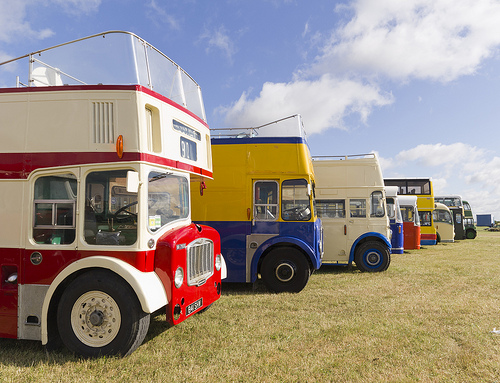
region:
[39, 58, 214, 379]
truck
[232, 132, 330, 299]
blue and yellow truck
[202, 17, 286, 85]
white clouds in blue sky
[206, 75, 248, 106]
white clouds in blue sky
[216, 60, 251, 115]
white clouds in blue sky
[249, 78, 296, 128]
white clouds in blue sky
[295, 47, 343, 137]
white clouds in blue sky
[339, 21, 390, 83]
white clouds in blue sky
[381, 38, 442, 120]
white clouds in blue sky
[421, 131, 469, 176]
white clouds in blue sky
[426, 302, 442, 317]
part of a field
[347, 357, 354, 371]
part of a lawn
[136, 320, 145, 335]
part of a wheel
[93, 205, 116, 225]
part of a window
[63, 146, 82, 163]
side of a bus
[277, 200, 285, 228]
edge of a bus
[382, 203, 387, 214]
edge of a bus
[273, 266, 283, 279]
part of a wheel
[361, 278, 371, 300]
part of a lawn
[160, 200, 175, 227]
part of a window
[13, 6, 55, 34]
white clouds in blue sky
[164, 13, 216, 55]
white clouds in blue sky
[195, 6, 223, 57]
white clouds in blue sky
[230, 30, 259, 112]
white clouds in blue sky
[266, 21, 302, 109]
white clouds in blue sky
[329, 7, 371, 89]
white clouds in blue sky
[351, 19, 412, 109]
white clouds in blue sky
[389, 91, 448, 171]
white clouds in blue sky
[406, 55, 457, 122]
white clouds in blue sky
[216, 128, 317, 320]
the RV is yellow and blue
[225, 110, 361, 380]
the RV is yellow and blue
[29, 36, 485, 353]
the buses are parked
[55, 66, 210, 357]
red and white truck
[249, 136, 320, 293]
yellow and blue bus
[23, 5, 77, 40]
white clouds in blue sky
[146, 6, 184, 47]
white clouds in blue sky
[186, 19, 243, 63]
white clouds in blue sky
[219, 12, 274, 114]
white clouds in blue sky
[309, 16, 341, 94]
white clouds in blue sky